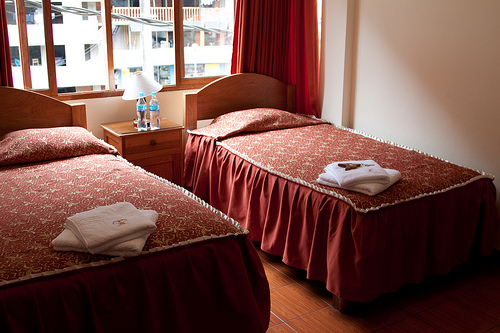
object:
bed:
[182, 71, 496, 307]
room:
[2, 0, 499, 333]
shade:
[122, 70, 164, 101]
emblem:
[112, 218, 128, 227]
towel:
[323, 159, 391, 187]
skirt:
[186, 134, 352, 236]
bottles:
[148, 92, 161, 131]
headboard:
[181, 72, 299, 121]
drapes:
[230, 0, 319, 118]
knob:
[150, 139, 158, 146]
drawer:
[123, 127, 186, 154]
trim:
[109, 153, 250, 233]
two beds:
[0, 73, 499, 333]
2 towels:
[50, 201, 159, 258]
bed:
[0, 86, 275, 333]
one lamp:
[122, 70, 165, 127]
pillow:
[0, 125, 120, 168]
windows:
[175, 0, 238, 85]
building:
[110, 12, 175, 88]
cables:
[52, 4, 102, 18]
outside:
[116, 9, 231, 87]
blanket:
[184, 106, 495, 216]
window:
[109, 0, 184, 90]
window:
[52, 0, 111, 97]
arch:
[197, 72, 287, 95]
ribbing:
[352, 174, 490, 216]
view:
[6, 1, 239, 91]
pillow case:
[185, 107, 333, 141]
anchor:
[338, 162, 363, 171]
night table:
[99, 114, 186, 190]